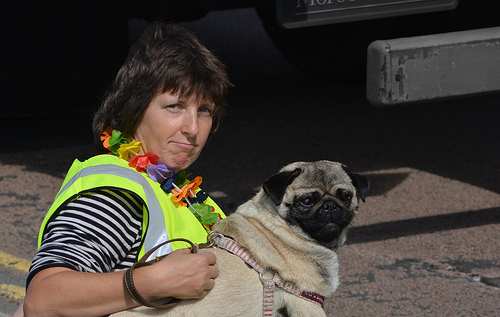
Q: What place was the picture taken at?
A: It was taken at the pavement.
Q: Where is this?
A: This is at the pavement.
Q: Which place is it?
A: It is a pavement.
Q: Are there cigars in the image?
A: No, there are no cigars.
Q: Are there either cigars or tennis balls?
A: No, there are no cigars or tennis balls.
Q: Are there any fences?
A: No, there are no fences.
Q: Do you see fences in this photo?
A: No, there are no fences.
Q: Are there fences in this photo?
A: No, there are no fences.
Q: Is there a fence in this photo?
A: No, there are no fences.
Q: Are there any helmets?
A: No, there are no helmets.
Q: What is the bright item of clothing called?
A: The clothing item is a vest.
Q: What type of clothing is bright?
A: The clothing is a vest.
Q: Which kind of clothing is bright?
A: The clothing is a vest.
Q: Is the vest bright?
A: Yes, the vest is bright.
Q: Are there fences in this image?
A: No, there are no fences.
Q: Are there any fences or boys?
A: No, there are no fences or boys.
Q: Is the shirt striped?
A: Yes, the shirt is striped.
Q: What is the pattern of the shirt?
A: The shirt is striped.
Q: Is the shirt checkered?
A: No, the shirt is striped.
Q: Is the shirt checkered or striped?
A: The shirt is striped.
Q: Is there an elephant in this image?
A: No, there are no elephants.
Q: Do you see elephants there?
A: No, there are no elephants.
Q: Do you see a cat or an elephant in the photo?
A: No, there are no elephants or cats.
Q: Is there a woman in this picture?
A: Yes, there is a woman.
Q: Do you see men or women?
A: Yes, there is a woman.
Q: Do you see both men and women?
A: No, there is a woman but no men.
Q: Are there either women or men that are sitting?
A: Yes, the woman is sitting.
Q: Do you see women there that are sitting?
A: Yes, there is a woman that is sitting.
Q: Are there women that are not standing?
A: Yes, there is a woman that is sitting.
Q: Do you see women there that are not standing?
A: Yes, there is a woman that is sitting .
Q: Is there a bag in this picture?
A: No, there are no bags.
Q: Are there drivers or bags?
A: No, there are no bags or drivers.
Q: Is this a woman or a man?
A: This is a woman.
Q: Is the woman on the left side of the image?
A: Yes, the woman is on the left of the image.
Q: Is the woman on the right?
A: No, the woman is on the left of the image.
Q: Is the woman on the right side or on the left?
A: The woman is on the left of the image.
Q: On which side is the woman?
A: The woman is on the left of the image.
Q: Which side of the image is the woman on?
A: The woman is on the left of the image.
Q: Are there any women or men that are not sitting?
A: No, there is a woman but she is sitting.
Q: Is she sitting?
A: Yes, the woman is sitting.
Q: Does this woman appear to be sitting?
A: Yes, the woman is sitting.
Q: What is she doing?
A: The woman is sitting.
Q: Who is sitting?
A: The woman is sitting.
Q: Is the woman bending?
A: No, the woman is sitting.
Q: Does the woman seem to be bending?
A: No, the woman is sitting.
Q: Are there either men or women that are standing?
A: No, there is a woman but she is sitting.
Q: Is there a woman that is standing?
A: No, there is a woman but she is sitting.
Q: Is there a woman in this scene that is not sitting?
A: No, there is a woman but she is sitting.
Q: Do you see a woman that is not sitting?
A: No, there is a woman but she is sitting.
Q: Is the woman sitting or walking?
A: The woman is sitting.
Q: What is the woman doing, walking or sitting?
A: The woman is sitting.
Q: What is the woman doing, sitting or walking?
A: The woman is sitting.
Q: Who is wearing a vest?
A: The woman is wearing a vest.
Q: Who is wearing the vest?
A: The woman is wearing a vest.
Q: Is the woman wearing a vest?
A: Yes, the woman is wearing a vest.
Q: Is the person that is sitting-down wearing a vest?
A: Yes, the woman is wearing a vest.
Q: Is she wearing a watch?
A: No, the woman is wearing a vest.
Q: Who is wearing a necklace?
A: The woman is wearing a necklace.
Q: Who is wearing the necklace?
A: The woman is wearing a necklace.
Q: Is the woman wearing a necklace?
A: Yes, the woman is wearing a necklace.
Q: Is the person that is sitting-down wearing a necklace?
A: Yes, the woman is wearing a necklace.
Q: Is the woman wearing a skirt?
A: No, the woman is wearing a necklace.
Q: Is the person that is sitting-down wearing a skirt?
A: No, the woman is wearing a necklace.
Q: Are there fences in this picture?
A: No, there are no fences.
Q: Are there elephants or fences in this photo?
A: No, there are no fences or elephants.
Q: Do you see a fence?
A: No, there are no fences.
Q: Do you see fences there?
A: No, there are no fences.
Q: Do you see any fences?
A: No, there are no fences.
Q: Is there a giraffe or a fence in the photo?
A: No, there are no fences or giraffes.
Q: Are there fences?
A: No, there are no fences.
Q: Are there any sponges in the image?
A: No, there are no sponges.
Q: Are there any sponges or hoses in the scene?
A: No, there are no sponges or hoses.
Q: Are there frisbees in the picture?
A: No, there are no frisbees.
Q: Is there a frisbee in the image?
A: No, there are no frisbees.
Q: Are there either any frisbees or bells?
A: No, there are no frisbees or bells.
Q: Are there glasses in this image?
A: No, there are no glasses.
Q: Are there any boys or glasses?
A: No, there are no glasses or boys.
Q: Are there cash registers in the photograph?
A: No, there are no cash registers.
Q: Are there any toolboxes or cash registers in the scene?
A: No, there are no cash registers or toolboxes.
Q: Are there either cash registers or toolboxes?
A: No, there are no cash registers or toolboxes.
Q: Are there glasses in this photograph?
A: No, there are no glasses.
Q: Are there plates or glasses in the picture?
A: No, there are no glasses or plates.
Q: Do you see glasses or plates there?
A: No, there are no glasses or plates.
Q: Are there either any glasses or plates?
A: No, there are no glasses or plates.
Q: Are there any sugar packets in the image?
A: No, there are no sugar packets.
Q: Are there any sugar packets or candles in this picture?
A: No, there are no sugar packets or candles.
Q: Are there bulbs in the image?
A: No, there are no bulbs.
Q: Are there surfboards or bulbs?
A: No, there are no bulbs or surfboards.